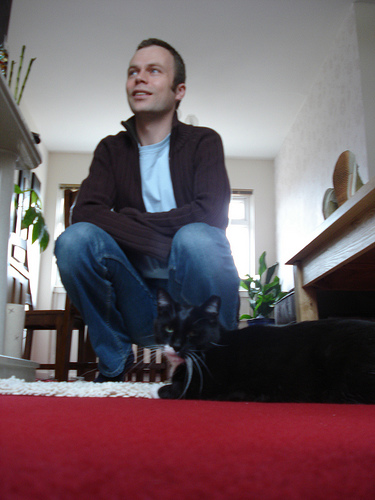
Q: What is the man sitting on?
A: A small chair.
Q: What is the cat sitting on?
A: The red carpet.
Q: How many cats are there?
A: One.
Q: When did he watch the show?
A: During the day.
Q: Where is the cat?
A: In the living room.